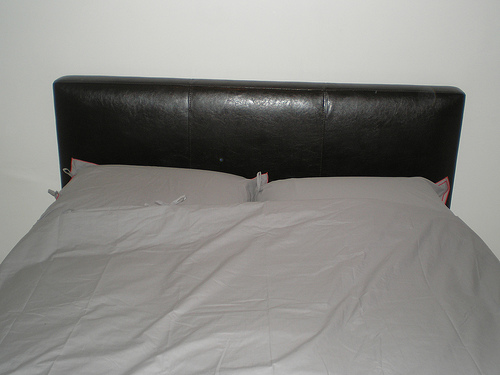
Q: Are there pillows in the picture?
A: Yes, there is a pillow.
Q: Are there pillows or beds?
A: Yes, there is a pillow.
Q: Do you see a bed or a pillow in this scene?
A: Yes, there is a pillow.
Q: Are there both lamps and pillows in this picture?
A: No, there is a pillow but no lamps.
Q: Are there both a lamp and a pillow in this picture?
A: No, there is a pillow but no lamps.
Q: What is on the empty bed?
A: The pillow is on the bed.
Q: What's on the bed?
A: The pillow is on the bed.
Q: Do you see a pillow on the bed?
A: Yes, there is a pillow on the bed.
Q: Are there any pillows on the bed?
A: Yes, there is a pillow on the bed.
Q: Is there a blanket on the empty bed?
A: No, there is a pillow on the bed.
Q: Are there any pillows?
A: Yes, there is a pillow.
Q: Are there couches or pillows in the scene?
A: Yes, there is a pillow.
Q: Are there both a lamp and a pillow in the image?
A: No, there is a pillow but no lamps.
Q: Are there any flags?
A: No, there are no flags.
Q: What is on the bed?
A: The pillow is on the bed.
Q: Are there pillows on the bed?
A: Yes, there is a pillow on the bed.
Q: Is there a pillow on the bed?
A: Yes, there is a pillow on the bed.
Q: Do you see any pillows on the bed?
A: Yes, there is a pillow on the bed.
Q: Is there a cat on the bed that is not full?
A: No, there is a pillow on the bed.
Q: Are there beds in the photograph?
A: Yes, there is a bed.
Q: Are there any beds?
A: Yes, there is a bed.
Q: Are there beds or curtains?
A: Yes, there is a bed.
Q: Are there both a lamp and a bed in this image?
A: No, there is a bed but no lamps.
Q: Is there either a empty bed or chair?
A: Yes, there is an empty bed.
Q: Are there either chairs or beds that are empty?
A: Yes, the bed is empty.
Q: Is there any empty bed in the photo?
A: Yes, there is an empty bed.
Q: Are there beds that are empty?
A: Yes, there is a bed that is empty.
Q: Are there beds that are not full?
A: Yes, there is a empty bed.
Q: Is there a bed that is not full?
A: Yes, there is a empty bed.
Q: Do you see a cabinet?
A: No, there are no cabinets.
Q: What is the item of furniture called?
A: The piece of furniture is a bed.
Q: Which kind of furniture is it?
A: The piece of furniture is a bed.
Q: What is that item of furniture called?
A: This is a bed.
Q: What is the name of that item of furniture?
A: This is a bed.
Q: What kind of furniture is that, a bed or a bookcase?
A: This is a bed.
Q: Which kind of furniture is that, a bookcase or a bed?
A: This is a bed.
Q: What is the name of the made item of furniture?
A: The piece of furniture is a bed.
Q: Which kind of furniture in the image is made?
A: The furniture is a bed.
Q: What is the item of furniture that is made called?
A: The piece of furniture is a bed.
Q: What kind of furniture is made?
A: The furniture is a bed.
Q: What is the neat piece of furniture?
A: The piece of furniture is a bed.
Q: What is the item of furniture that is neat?
A: The piece of furniture is a bed.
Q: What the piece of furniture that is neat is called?
A: The piece of furniture is a bed.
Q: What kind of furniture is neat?
A: The furniture is a bed.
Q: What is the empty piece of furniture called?
A: The piece of furniture is a bed.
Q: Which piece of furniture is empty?
A: The piece of furniture is a bed.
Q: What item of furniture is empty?
A: The piece of furniture is a bed.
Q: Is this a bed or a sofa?
A: This is a bed.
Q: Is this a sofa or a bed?
A: This is a bed.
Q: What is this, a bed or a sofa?
A: This is a bed.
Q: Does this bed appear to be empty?
A: Yes, the bed is empty.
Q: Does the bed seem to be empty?
A: Yes, the bed is empty.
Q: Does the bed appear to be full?
A: No, the bed is empty.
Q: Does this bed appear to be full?
A: No, the bed is empty.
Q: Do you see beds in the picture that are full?
A: No, there is a bed but it is empty.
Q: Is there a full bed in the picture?
A: No, there is a bed but it is empty.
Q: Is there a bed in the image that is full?
A: No, there is a bed but it is empty.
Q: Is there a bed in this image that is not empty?
A: No, there is a bed but it is empty.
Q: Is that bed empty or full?
A: The bed is empty.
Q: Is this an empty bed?
A: Yes, this is an empty bed.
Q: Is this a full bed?
A: No, this is an empty bed.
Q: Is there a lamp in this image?
A: No, there are no lamps.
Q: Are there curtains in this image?
A: No, there are no curtains.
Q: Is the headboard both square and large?
A: Yes, the headboard is square and large.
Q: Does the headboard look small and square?
A: No, the headboard is square but large.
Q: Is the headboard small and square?
A: No, the headboard is square but large.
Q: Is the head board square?
A: Yes, the head board is square.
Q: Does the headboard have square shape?
A: Yes, the headboard is square.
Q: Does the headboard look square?
A: Yes, the headboard is square.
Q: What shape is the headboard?
A: The headboard is square.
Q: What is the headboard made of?
A: The head board is made of leather.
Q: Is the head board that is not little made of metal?
A: No, the headboard is made of leather.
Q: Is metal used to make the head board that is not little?
A: No, the headboard is made of leather.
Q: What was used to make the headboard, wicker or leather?
A: The headboard is made of leather.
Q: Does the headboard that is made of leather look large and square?
A: Yes, the head board is large and square.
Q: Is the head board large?
A: Yes, the head board is large.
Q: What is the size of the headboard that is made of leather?
A: The headboard is large.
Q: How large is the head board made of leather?
A: The headboard is large.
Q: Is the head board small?
A: No, the head board is large.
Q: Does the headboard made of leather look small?
A: No, the headboard is large.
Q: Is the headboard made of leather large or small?
A: The headboard is large.